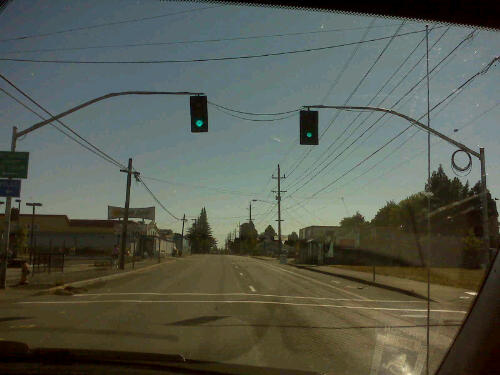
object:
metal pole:
[118, 157, 141, 272]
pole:
[118, 157, 133, 273]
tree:
[183, 205, 218, 254]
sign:
[0, 178, 22, 198]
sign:
[0, 150, 29, 180]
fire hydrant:
[18, 261, 34, 285]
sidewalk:
[3, 245, 174, 304]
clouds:
[166, 162, 241, 214]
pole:
[277, 163, 283, 260]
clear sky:
[0, 0, 498, 250]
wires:
[238, 18, 375, 227]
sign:
[298, 109, 320, 145]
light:
[299, 110, 319, 146]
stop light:
[189, 93, 208, 133]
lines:
[19, 299, 465, 314]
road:
[0, 253, 500, 375]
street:
[0, 252, 468, 374]